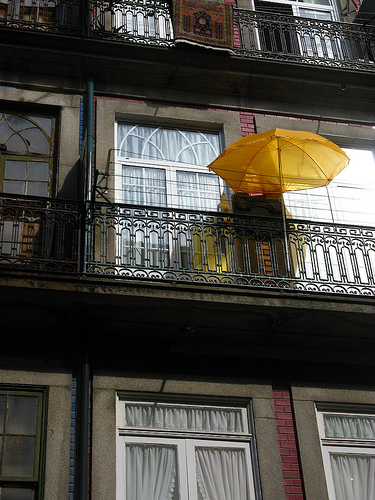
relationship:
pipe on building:
[72, 69, 102, 500] [0, 1, 375, 500]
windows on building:
[116, 392, 373, 499] [0, 1, 375, 500]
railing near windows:
[0, 191, 374, 304] [116, 392, 373, 499]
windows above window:
[116, 392, 373, 499] [114, 441, 187, 498]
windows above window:
[116, 392, 373, 499] [188, 438, 261, 499]